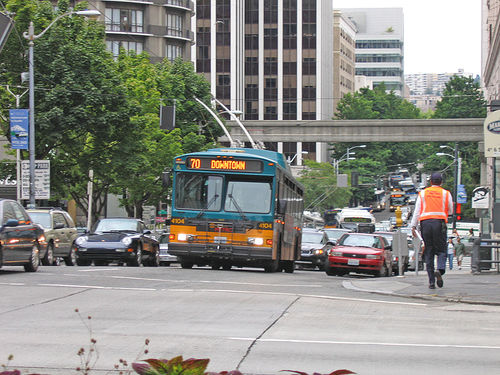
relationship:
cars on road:
[74, 218, 152, 264] [3, 264, 499, 372]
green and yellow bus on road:
[167, 145, 307, 273] [3, 264, 499, 372]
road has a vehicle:
[3, 264, 499, 372] [326, 227, 393, 277]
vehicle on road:
[29, 207, 79, 270] [3, 264, 499, 372]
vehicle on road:
[298, 227, 330, 273] [3, 264, 499, 372]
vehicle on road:
[1, 198, 49, 278] [3, 264, 499, 372]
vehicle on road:
[387, 190, 409, 212] [3, 264, 499, 372]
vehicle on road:
[335, 206, 378, 230] [3, 264, 499, 372]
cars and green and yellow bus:
[0, 195, 171, 271] [167, 145, 307, 273]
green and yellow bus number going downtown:
[167, 145, 307, 273] [3, 141, 413, 371]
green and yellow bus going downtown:
[167, 145, 307, 276] [3, 6, 493, 374]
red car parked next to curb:
[326, 227, 393, 277] [343, 230, 419, 296]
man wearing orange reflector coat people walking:
[410, 172, 455, 294] [409, 172, 475, 292]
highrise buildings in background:
[105, 1, 500, 146] [194, 9, 499, 117]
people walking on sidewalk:
[409, 172, 475, 292] [389, 230, 495, 294]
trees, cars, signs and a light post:
[3, 6, 493, 374] [19, 6, 101, 208]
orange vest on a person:
[409, 184, 457, 227] [410, 172, 455, 294]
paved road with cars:
[3, 264, 499, 372] [3, 120, 418, 280]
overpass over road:
[214, 117, 486, 145] [3, 264, 499, 372]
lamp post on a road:
[19, 6, 101, 208] [3, 264, 499, 372]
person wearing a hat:
[410, 172, 455, 294] [430, 171, 443, 181]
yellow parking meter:
[393, 206, 408, 230] [395, 205, 405, 281]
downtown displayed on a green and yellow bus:
[3, 6, 493, 374] [167, 145, 307, 273]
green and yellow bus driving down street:
[167, 145, 307, 273] [3, 264, 499, 372]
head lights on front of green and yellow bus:
[171, 228, 274, 247] [167, 145, 307, 273]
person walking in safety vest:
[410, 172, 455, 294] [409, 184, 457, 227]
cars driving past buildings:
[74, 218, 152, 264] [105, 1, 500, 146]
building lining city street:
[105, 1, 500, 146] [3, 264, 499, 372]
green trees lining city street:
[3, 1, 165, 219] [3, 264, 499, 372]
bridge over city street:
[214, 117, 486, 145] [3, 264, 499, 372]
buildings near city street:
[105, 1, 500, 146] [3, 264, 499, 372]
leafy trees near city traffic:
[3, 1, 165, 219] [3, 120, 418, 280]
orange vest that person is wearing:
[409, 184, 457, 227] [410, 172, 455, 294]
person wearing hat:
[410, 172, 455, 294] [430, 171, 443, 181]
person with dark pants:
[410, 172, 455, 294] [419, 221, 448, 291]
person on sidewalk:
[410, 172, 455, 294] [389, 230, 495, 294]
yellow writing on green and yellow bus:
[170, 218, 277, 245] [167, 145, 307, 273]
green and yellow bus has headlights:
[167, 145, 307, 273] [171, 228, 274, 247]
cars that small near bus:
[74, 218, 152, 264] [72, 143, 305, 278]